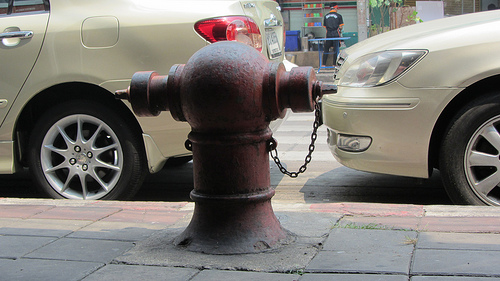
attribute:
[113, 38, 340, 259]
hydrant — red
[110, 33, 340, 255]
fire hydrant — old, weathered